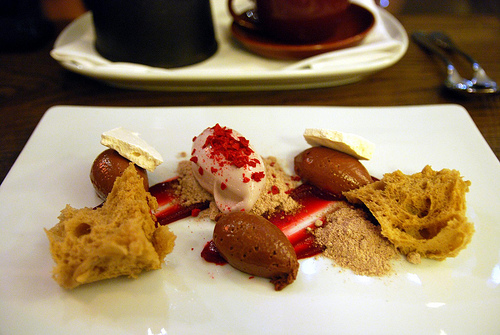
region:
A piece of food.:
[211, 211, 310, 284]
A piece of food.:
[315, 205, 397, 283]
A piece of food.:
[349, 157, 469, 267]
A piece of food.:
[291, 148, 374, 195]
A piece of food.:
[304, 130, 364, 162]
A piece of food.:
[100, 124, 174, 167]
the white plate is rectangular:
[3, 100, 486, 333]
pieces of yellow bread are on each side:
[46, 162, 468, 272]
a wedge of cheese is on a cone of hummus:
[91, 122, 161, 204]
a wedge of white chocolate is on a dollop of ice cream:
[291, 124, 375, 203]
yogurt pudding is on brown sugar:
[176, 122, 298, 227]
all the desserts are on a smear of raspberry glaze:
[86, 161, 353, 270]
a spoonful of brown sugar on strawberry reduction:
[297, 205, 394, 278]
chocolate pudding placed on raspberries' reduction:
[211, 210, 297, 288]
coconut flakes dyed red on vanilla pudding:
[191, 122, 257, 172]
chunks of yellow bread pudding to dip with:
[48, 165, 176, 287]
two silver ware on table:
[430, 31, 480, 108]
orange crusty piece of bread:
[43, 178, 159, 297]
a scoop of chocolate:
[214, 214, 299, 301]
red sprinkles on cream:
[200, 120, 262, 182]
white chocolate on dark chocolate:
[101, 123, 150, 158]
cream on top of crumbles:
[178, 120, 269, 225]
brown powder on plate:
[320, 219, 393, 282]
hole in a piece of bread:
[52, 213, 115, 254]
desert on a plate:
[82, 132, 433, 329]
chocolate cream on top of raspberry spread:
[230, 193, 322, 256]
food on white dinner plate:
[17, 88, 367, 330]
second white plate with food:
[60, 17, 440, 109]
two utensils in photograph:
[410, 8, 498, 116]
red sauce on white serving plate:
[202, 127, 359, 279]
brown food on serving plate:
[41, 148, 169, 278]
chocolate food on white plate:
[181, 154, 312, 309]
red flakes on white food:
[198, 81, 279, 225]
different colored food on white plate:
[57, 105, 498, 290]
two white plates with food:
[44, 1, 464, 333]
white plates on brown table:
[37, 27, 377, 328]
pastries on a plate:
[27, 98, 482, 318]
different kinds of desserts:
[22, 92, 492, 315]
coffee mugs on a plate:
[38, 4, 420, 94]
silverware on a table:
[389, 18, 497, 110]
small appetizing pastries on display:
[33, 101, 473, 298]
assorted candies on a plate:
[26, 107, 488, 300]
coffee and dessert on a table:
[37, 3, 489, 310]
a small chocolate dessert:
[197, 200, 305, 295]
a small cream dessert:
[176, 107, 276, 215]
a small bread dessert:
[322, 129, 485, 271]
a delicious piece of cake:
[395, 166, 472, 243]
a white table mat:
[40, 123, 100, 192]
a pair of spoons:
[431, 31, 494, 95]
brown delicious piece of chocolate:
[219, 220, 295, 262]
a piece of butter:
[105, 131, 165, 161]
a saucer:
[245, 31, 333, 61]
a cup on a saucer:
[227, 0, 365, 47]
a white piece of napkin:
[42, 39, 109, 81]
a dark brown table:
[385, 72, 445, 97]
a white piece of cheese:
[207, 174, 261, 201]